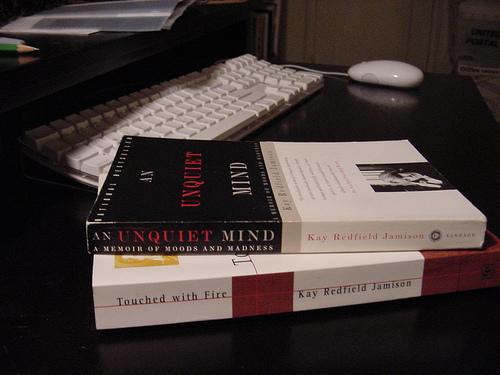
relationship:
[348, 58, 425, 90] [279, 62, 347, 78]
mouse connected by wire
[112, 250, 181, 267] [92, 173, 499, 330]
mark on book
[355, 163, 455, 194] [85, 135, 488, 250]
photo on book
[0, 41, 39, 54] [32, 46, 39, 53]
pencil has lead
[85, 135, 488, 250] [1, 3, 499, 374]
book on desk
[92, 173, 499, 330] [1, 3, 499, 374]
book on desk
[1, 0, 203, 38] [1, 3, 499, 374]
paper on desk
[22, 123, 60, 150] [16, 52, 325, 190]
button on keyboard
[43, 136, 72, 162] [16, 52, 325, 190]
button on keyboard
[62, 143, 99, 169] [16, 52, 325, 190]
button on keyboard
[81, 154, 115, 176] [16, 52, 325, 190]
button on keyboard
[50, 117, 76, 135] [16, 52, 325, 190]
button on keyboard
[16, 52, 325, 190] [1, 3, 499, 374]
keyboard on desk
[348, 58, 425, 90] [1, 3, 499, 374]
mouse on desk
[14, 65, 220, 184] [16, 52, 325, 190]
shadow on keyboard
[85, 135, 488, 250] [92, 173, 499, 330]
book on top of book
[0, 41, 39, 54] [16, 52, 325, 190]
pencil above keyboard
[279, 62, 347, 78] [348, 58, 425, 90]
wire attached to mouse